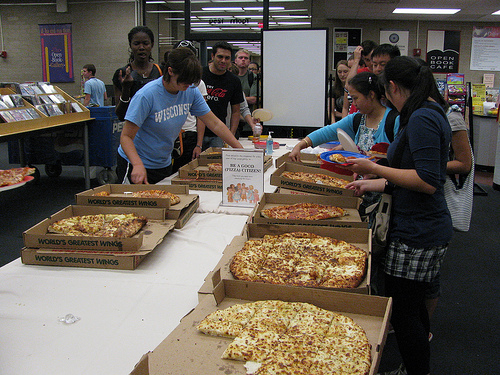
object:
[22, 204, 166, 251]
box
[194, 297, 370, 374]
pizza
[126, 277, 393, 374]
box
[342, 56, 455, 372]
girl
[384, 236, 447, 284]
skirt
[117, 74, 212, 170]
shirt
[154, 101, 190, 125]
lettering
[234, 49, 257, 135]
person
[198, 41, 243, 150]
person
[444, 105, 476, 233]
purse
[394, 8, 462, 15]
light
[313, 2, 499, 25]
ceiling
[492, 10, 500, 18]
light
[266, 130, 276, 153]
hand sanitizer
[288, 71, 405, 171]
person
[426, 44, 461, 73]
sign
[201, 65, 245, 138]
shirt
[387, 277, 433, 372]
leggings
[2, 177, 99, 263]
carpet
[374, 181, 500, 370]
carpet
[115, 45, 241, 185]
woman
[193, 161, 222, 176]
pizza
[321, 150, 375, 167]
dish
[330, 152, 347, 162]
slice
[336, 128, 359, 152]
plate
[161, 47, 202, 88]
hair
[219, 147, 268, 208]
sign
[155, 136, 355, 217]
table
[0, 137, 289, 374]
table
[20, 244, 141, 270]
box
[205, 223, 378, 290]
box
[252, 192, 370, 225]
box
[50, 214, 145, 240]
pizza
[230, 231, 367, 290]
pizza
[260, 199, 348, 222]
pizza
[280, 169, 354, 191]
pizza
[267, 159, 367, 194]
box